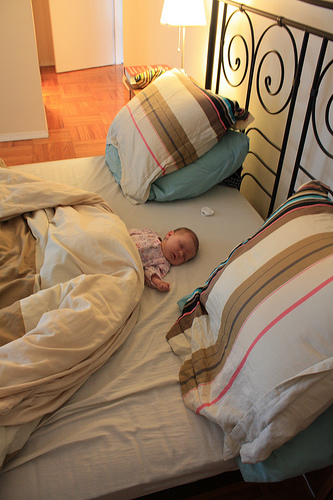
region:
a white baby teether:
[192, 199, 222, 225]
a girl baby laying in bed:
[118, 210, 214, 328]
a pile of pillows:
[83, 61, 266, 217]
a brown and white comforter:
[0, 166, 154, 438]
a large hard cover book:
[117, 56, 179, 87]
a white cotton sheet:
[74, 387, 213, 485]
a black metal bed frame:
[194, 2, 331, 224]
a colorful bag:
[125, 63, 170, 94]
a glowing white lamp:
[149, 0, 229, 91]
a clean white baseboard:
[1, 122, 59, 145]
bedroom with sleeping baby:
[0, 0, 331, 499]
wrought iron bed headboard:
[204, 0, 331, 221]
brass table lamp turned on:
[160, 0, 208, 67]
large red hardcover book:
[122, 63, 171, 79]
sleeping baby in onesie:
[126, 226, 200, 292]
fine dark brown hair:
[172, 226, 198, 261]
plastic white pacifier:
[200, 205, 215, 216]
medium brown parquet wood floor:
[0, 65, 130, 167]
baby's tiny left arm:
[142, 266, 170, 292]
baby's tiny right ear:
[164, 230, 174, 239]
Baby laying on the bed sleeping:
[106, 200, 229, 308]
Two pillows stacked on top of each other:
[94, 94, 250, 204]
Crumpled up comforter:
[11, 175, 146, 402]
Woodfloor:
[63, 73, 123, 138]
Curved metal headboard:
[210, 9, 326, 155]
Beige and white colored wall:
[7, 9, 50, 150]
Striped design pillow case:
[116, 100, 207, 155]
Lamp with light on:
[159, 2, 211, 63]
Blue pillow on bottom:
[238, 431, 327, 467]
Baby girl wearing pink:
[118, 218, 198, 342]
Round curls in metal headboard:
[219, 5, 300, 116]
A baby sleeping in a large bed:
[126, 224, 200, 293]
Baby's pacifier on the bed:
[200, 202, 216, 218]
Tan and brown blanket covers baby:
[1, 161, 146, 469]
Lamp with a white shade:
[156, 0, 207, 68]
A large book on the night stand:
[121, 63, 172, 83]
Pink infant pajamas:
[127, 224, 170, 281]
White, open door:
[46, 0, 123, 75]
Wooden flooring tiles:
[0, 63, 122, 166]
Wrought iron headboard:
[204, 0, 331, 221]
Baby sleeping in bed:
[124, 220, 198, 298]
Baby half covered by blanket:
[74, 203, 208, 317]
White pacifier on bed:
[190, 202, 224, 225]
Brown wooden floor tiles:
[62, 89, 102, 143]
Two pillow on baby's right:
[93, 67, 253, 210]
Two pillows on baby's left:
[184, 185, 330, 476]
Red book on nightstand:
[118, 61, 180, 87]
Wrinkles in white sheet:
[101, 356, 187, 444]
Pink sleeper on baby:
[128, 215, 168, 292]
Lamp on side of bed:
[153, 0, 208, 78]